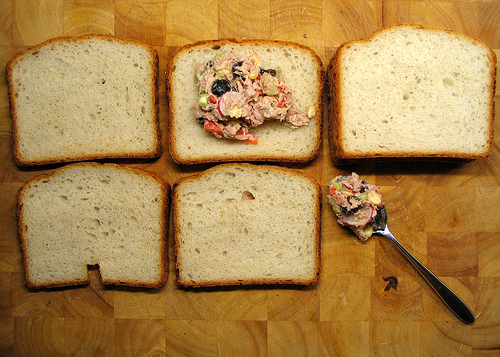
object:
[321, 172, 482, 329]
spoon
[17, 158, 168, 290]
bread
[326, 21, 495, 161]
bread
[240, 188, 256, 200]
mark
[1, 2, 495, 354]
table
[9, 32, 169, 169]
bread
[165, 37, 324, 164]
bread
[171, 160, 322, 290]
bread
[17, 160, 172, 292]
bread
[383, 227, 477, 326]
handle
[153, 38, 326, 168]
bread